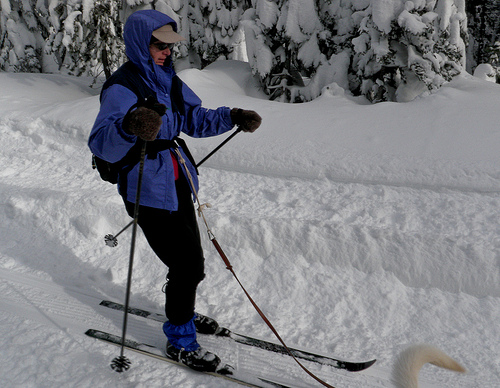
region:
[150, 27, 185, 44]
The brim of the beige hat the skier is wearing.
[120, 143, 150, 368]
The ski pole in the skier's left hand.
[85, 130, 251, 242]
The ski pole in the skier's right hand.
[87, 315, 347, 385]
The skis the skier is standing on.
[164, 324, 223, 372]
The skier's left boot.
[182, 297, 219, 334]
The skier's right boot.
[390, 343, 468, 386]
The tail of the dog.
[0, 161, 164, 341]
The shadow of the skier behind him on the ground.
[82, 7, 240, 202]
The blue jacket the skier is wearing.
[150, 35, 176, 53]
The sunglasses the skier is wearing.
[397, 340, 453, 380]
tail of the dog.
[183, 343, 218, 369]
boot on woman's foot.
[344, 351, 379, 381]
tip of the left ski.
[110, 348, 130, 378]
bottom of the ski pole.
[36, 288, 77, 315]
ski tracks in the snow.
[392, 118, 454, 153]
snow on the ground.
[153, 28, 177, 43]
cap on person's head.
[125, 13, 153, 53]
hood over person's head.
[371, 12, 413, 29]
snow on the tree.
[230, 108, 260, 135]
glove on person's hand.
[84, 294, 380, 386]
Pair of black skis with some snow on them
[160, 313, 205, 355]
Blue cuff of snow pants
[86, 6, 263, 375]
Man on skis in a blue ski jacket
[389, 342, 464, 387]
White dog tail most likely a husky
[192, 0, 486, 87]
Trees cover in snow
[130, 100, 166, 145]
Ski glove gripping ski stick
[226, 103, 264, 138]
Ski glove gripping ski stick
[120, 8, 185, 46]
Light brown hat cover with a blue hood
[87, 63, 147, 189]
Black backpack on a man skiing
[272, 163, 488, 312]
Fresh snow on a ski track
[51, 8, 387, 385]
a person skiing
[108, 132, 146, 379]
a ski pole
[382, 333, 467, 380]
a tail of an animal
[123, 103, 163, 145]
a brown glove a person is wearing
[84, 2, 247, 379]
a person in black snow pants skiing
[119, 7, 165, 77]
a hoodie a person is wearing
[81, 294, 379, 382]
a pair of skiis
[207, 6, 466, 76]
trees covered with snow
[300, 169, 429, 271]
white snow on the ground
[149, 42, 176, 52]
sunglasses a woman is wearing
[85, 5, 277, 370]
man on skies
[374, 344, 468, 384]
a dogs tail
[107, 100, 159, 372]
ski pole in right hand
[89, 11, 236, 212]
blue jascket with hood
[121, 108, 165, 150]
a gloved hand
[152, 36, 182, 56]
a pair of sunglasses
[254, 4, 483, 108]
trees covered in snow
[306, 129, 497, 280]
trackes in the snow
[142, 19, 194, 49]
a skiers hat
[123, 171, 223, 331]
pair of black pants